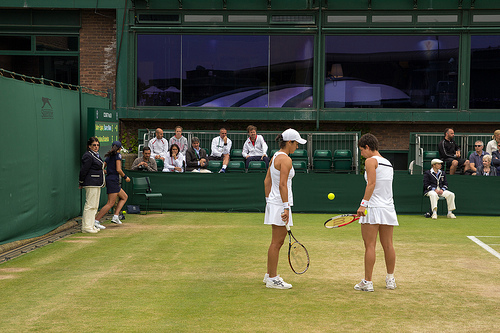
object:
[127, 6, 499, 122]
glass wall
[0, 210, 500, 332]
tennis court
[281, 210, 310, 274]
racket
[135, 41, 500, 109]
windows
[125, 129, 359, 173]
bleachers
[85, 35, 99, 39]
bricks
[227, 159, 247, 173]
seating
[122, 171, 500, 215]
screen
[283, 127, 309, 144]
cap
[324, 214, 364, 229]
racket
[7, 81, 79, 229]
wall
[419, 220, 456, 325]
grass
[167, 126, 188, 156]
spectators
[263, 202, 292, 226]
dresses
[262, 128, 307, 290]
ladies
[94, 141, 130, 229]
ladies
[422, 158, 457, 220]
official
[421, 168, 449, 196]
blazer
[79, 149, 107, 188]
blazer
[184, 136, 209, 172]
specatators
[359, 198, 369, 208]
sweatband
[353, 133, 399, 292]
lady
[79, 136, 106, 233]
lady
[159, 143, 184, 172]
people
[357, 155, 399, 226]
uniform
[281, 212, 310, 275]
tennis racket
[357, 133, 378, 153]
hair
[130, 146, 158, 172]
people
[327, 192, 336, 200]
ball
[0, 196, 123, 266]
sideline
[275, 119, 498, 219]
stands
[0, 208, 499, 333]
court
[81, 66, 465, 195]
background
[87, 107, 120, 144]
scoreboard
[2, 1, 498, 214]
building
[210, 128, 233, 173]
spectator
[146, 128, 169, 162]
spectator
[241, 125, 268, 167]
spectator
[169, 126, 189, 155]
spectator